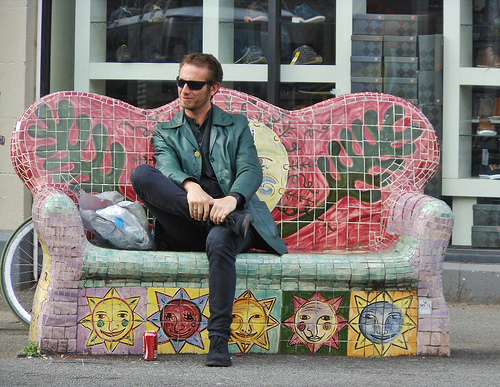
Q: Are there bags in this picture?
A: Yes, there is a bag.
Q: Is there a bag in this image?
A: Yes, there is a bag.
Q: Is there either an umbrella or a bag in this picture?
A: Yes, there is a bag.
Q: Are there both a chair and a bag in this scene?
A: No, there is a bag but no chairs.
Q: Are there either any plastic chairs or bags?
A: Yes, there is a plastic bag.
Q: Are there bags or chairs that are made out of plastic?
A: Yes, the bag is made of plastic.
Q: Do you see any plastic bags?
A: Yes, there is a bag that is made of plastic.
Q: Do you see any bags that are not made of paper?
A: Yes, there is a bag that is made of plastic.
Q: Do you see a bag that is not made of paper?
A: Yes, there is a bag that is made of plastic.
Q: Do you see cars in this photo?
A: No, there are no cars.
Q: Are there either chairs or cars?
A: No, there are no cars or chairs.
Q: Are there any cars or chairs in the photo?
A: No, there are no cars or chairs.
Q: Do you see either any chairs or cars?
A: No, there are no cars or chairs.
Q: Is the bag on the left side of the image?
A: Yes, the bag is on the left of the image.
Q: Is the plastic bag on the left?
A: Yes, the bag is on the left of the image.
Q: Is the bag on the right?
A: No, the bag is on the left of the image.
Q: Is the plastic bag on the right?
A: No, the bag is on the left of the image.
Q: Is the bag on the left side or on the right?
A: The bag is on the left of the image.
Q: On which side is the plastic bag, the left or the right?
A: The bag is on the left of the image.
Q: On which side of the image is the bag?
A: The bag is on the left of the image.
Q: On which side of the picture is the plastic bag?
A: The bag is on the left of the image.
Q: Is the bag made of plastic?
A: Yes, the bag is made of plastic.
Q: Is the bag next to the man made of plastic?
A: Yes, the bag is made of plastic.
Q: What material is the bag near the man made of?
A: The bag is made of plastic.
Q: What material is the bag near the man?
A: The bag is made of plastic.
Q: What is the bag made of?
A: The bag is made of plastic.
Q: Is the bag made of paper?
A: No, the bag is made of plastic.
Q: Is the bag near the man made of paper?
A: No, the bag is made of plastic.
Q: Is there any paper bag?
A: No, there is a bag but it is made of plastic.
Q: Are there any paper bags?
A: No, there is a bag but it is made of plastic.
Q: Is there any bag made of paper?
A: No, there is a bag but it is made of plastic.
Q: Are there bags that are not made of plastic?
A: No, there is a bag but it is made of plastic.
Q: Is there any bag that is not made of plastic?
A: No, there is a bag but it is made of plastic.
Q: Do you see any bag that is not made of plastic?
A: No, there is a bag but it is made of plastic.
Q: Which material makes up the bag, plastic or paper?
A: The bag is made of plastic.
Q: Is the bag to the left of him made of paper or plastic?
A: The bag is made of plastic.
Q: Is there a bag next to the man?
A: Yes, there is a bag next to the man.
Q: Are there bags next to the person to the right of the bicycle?
A: Yes, there is a bag next to the man.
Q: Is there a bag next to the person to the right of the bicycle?
A: Yes, there is a bag next to the man.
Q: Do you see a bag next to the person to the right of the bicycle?
A: Yes, there is a bag next to the man.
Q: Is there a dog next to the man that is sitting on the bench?
A: No, there is a bag next to the man.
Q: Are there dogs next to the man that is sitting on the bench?
A: No, there is a bag next to the man.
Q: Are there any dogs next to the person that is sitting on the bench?
A: No, there is a bag next to the man.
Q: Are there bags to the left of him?
A: Yes, there is a bag to the left of the man.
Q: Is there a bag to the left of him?
A: Yes, there is a bag to the left of the man.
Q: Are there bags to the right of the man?
A: No, the bag is to the left of the man.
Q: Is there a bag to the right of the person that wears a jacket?
A: No, the bag is to the left of the man.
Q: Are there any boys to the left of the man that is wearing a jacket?
A: No, there is a bag to the left of the man.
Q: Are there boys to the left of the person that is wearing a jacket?
A: No, there is a bag to the left of the man.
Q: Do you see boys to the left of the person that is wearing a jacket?
A: No, there is a bag to the left of the man.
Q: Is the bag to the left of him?
A: Yes, the bag is to the left of a man.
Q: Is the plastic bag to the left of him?
A: Yes, the bag is to the left of a man.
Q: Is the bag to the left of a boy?
A: No, the bag is to the left of a man.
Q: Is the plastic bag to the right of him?
A: No, the bag is to the left of the man.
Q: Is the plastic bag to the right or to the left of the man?
A: The bag is to the left of the man.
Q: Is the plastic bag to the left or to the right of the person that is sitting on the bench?
A: The bag is to the left of the man.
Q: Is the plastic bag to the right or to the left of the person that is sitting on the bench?
A: The bag is to the left of the man.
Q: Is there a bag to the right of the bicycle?
A: Yes, there is a bag to the right of the bicycle.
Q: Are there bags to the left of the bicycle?
A: No, the bag is to the right of the bicycle.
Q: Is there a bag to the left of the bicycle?
A: No, the bag is to the right of the bicycle.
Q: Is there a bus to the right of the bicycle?
A: No, there is a bag to the right of the bicycle.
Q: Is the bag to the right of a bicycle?
A: Yes, the bag is to the right of a bicycle.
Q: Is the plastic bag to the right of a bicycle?
A: Yes, the bag is to the right of a bicycle.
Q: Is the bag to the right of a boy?
A: No, the bag is to the right of a bicycle.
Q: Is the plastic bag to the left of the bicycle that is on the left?
A: No, the bag is to the right of the bicycle.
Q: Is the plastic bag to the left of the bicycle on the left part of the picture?
A: No, the bag is to the right of the bicycle.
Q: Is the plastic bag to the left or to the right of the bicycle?
A: The bag is to the right of the bicycle.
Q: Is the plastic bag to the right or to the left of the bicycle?
A: The bag is to the right of the bicycle.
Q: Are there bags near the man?
A: Yes, there is a bag near the man.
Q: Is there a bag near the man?
A: Yes, there is a bag near the man.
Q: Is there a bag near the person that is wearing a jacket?
A: Yes, there is a bag near the man.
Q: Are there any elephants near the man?
A: No, there is a bag near the man.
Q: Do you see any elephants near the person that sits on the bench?
A: No, there is a bag near the man.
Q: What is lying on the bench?
A: The bag is lying on the bench.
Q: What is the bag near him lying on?
A: The bag is lying on the bench.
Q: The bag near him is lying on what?
A: The bag is lying on the bench.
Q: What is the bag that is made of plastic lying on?
A: The bag is lying on the bench.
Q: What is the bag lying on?
A: The bag is lying on the bench.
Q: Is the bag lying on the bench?
A: Yes, the bag is lying on the bench.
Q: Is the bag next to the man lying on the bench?
A: Yes, the bag is lying on the bench.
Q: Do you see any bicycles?
A: Yes, there is a bicycle.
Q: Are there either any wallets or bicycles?
A: Yes, there is a bicycle.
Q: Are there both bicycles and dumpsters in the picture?
A: No, there is a bicycle but no dumpsters.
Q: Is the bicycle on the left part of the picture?
A: Yes, the bicycle is on the left of the image.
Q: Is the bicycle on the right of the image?
A: No, the bicycle is on the left of the image.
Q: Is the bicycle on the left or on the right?
A: The bicycle is on the left of the image.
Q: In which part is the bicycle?
A: The bicycle is on the left of the image.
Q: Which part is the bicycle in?
A: The bicycle is on the left of the image.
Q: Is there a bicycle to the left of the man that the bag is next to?
A: Yes, there is a bicycle to the left of the man.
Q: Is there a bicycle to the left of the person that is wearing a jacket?
A: Yes, there is a bicycle to the left of the man.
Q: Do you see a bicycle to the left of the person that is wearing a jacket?
A: Yes, there is a bicycle to the left of the man.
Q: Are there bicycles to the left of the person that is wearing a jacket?
A: Yes, there is a bicycle to the left of the man.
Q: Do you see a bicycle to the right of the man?
A: No, the bicycle is to the left of the man.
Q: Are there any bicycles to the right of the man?
A: No, the bicycle is to the left of the man.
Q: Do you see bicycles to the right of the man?
A: No, the bicycle is to the left of the man.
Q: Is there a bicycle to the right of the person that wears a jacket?
A: No, the bicycle is to the left of the man.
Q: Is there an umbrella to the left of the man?
A: No, there is a bicycle to the left of the man.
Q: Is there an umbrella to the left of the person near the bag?
A: No, there is a bicycle to the left of the man.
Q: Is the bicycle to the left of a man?
A: Yes, the bicycle is to the left of a man.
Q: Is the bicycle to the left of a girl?
A: No, the bicycle is to the left of a man.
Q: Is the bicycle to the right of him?
A: No, the bicycle is to the left of the man.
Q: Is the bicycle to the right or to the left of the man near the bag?
A: The bicycle is to the left of the man.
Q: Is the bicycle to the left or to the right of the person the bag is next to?
A: The bicycle is to the left of the man.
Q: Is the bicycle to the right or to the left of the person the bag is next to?
A: The bicycle is to the left of the man.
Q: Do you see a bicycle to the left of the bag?
A: Yes, there is a bicycle to the left of the bag.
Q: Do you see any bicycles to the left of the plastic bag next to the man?
A: Yes, there is a bicycle to the left of the bag.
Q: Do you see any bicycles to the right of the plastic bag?
A: No, the bicycle is to the left of the bag.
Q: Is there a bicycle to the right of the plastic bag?
A: No, the bicycle is to the left of the bag.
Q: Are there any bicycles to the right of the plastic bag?
A: No, the bicycle is to the left of the bag.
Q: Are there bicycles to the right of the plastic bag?
A: No, the bicycle is to the left of the bag.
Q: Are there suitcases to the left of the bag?
A: No, there is a bicycle to the left of the bag.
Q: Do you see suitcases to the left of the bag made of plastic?
A: No, there is a bicycle to the left of the bag.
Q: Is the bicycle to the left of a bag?
A: Yes, the bicycle is to the left of a bag.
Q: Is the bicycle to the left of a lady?
A: No, the bicycle is to the left of a bag.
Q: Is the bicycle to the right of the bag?
A: No, the bicycle is to the left of the bag.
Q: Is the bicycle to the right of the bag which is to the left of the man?
A: No, the bicycle is to the left of the bag.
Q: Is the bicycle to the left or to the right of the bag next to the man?
A: The bicycle is to the left of the bag.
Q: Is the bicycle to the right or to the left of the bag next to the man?
A: The bicycle is to the left of the bag.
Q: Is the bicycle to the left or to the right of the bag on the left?
A: The bicycle is to the left of the bag.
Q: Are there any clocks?
A: No, there are no clocks.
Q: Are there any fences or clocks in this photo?
A: No, there are no clocks or fences.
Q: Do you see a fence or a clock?
A: No, there are no clocks or fences.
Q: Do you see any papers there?
A: No, there are no papers.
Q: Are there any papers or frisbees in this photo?
A: No, there are no papers or frisbees.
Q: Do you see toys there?
A: No, there are no toys.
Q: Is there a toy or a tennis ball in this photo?
A: No, there are no toys or tennis balls.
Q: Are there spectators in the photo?
A: No, there are no spectators.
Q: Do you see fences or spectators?
A: No, there are no spectators or fences.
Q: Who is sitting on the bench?
A: The man is sitting on the bench.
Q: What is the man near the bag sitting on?
A: The man is sitting on the bench.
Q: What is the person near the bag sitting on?
A: The man is sitting on the bench.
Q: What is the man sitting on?
A: The man is sitting on the bench.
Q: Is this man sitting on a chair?
A: No, the man is sitting on the bench.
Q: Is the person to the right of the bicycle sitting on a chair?
A: No, the man is sitting on the bench.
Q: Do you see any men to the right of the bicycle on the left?
A: Yes, there is a man to the right of the bicycle.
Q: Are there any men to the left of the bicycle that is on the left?
A: No, the man is to the right of the bicycle.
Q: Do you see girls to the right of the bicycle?
A: No, there is a man to the right of the bicycle.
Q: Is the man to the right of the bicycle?
A: Yes, the man is to the right of the bicycle.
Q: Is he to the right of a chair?
A: No, the man is to the right of the bicycle.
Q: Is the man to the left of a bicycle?
A: No, the man is to the right of a bicycle.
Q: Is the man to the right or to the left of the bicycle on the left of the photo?
A: The man is to the right of the bicycle.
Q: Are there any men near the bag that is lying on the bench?
A: Yes, there is a man near the bag.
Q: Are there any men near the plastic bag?
A: Yes, there is a man near the bag.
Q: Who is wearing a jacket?
A: The man is wearing a jacket.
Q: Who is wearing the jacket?
A: The man is wearing a jacket.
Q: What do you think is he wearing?
A: The man is wearing a jacket.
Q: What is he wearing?
A: The man is wearing a jacket.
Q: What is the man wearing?
A: The man is wearing a jacket.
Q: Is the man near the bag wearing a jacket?
A: Yes, the man is wearing a jacket.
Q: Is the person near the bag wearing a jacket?
A: Yes, the man is wearing a jacket.